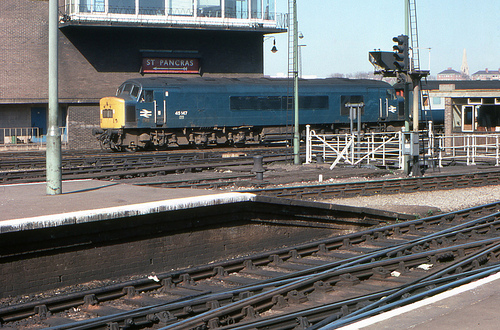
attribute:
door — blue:
[30, 108, 48, 142]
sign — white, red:
[140, 55, 205, 71]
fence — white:
[304, 125, 488, 167]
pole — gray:
[39, 22, 66, 198]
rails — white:
[303, 125, 401, 168]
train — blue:
[93, 70, 498, 151]